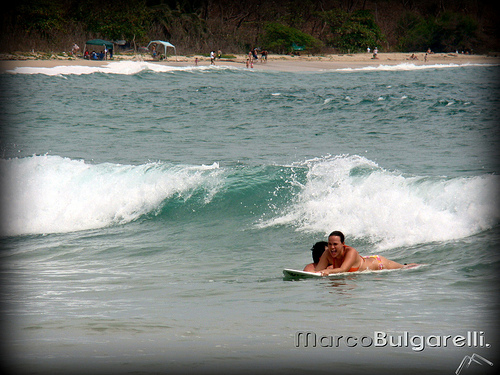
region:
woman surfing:
[280, 230, 420, 301]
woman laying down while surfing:
[267, 222, 423, 285]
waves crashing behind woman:
[2, 155, 487, 243]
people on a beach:
[2, 26, 478, 67]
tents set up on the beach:
[76, 31, 177, 67]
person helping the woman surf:
[305, 236, 321, 271]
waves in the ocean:
[26, 73, 481, 134]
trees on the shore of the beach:
[0, 10, 470, 51]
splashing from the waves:
[280, 150, 351, 205]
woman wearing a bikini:
[325, 239, 412, 269]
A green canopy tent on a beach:
[66, 33, 122, 67]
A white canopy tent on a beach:
[142, 37, 179, 64]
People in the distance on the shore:
[200, 39, 280, 73]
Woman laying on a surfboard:
[282, 230, 422, 281]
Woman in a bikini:
[312, 229, 407, 276]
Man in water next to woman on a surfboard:
[302, 235, 333, 275]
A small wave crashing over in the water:
[10, 149, 485, 244]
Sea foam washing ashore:
[6, 59, 205, 78]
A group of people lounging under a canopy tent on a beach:
[77, 37, 119, 64]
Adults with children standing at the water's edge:
[188, 46, 259, 73]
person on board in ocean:
[265, 212, 422, 284]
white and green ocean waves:
[361, 122, 406, 149]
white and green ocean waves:
[245, 308, 303, 362]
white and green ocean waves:
[57, 81, 127, 183]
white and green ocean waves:
[151, 165, 223, 257]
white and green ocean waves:
[190, 139, 238, 177]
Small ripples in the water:
[28, 96, 75, 124]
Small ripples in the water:
[358, 84, 418, 127]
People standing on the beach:
[193, 41, 467, 73]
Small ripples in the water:
[268, 81, 325, 147]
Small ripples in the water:
[58, 278, 105, 329]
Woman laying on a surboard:
[273, 212, 420, 311]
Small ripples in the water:
[207, 312, 272, 352]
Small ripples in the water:
[150, 216, 222, 266]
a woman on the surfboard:
[254, 213, 435, 313]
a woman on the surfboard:
[267, 223, 447, 315]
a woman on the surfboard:
[265, 230, 413, 301]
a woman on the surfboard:
[277, 226, 419, 297]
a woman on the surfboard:
[279, 225, 404, 307]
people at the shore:
[178, 32, 445, 74]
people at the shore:
[182, 23, 419, 77]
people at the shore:
[134, 22, 439, 100]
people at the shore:
[176, 40, 447, 80]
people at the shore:
[168, 26, 473, 113]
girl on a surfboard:
[322, 231, 414, 272]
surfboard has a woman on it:
[324, 235, 422, 275]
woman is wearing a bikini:
[326, 227, 408, 272]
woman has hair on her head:
[323, 228, 352, 242]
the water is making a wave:
[191, 124, 482, 254]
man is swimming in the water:
[306, 235, 334, 270]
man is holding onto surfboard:
[311, 236, 331, 276]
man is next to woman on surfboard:
[309, 233, 329, 275]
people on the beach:
[195, 45, 449, 67]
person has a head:
[325, 232, 343, 254]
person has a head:
[309, 242, 326, 262]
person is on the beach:
[245, 54, 253, 65]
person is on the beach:
[259, 50, 266, 61]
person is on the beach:
[249, 49, 255, 61]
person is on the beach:
[209, 50, 214, 63]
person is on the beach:
[153, 44, 157, 59]